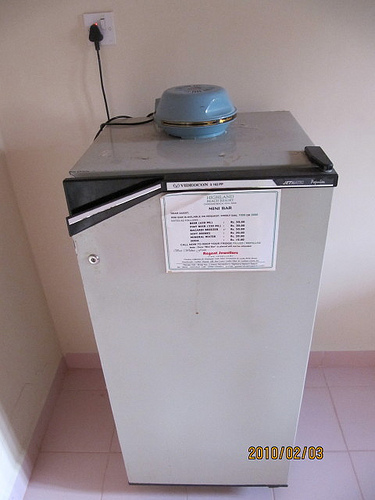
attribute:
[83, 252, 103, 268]
metal lock — silver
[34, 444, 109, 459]
gray line — grey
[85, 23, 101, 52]
black plug — plugged in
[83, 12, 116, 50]
white outlet — square 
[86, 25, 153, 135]
electrical cord — long , black 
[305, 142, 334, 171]
black fastener — large 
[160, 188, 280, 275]
square logo — white 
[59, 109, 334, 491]
refrigerator — black, white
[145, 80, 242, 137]
appliance — blue 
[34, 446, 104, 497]
floor — white 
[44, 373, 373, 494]
floor — white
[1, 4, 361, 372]
wall — white